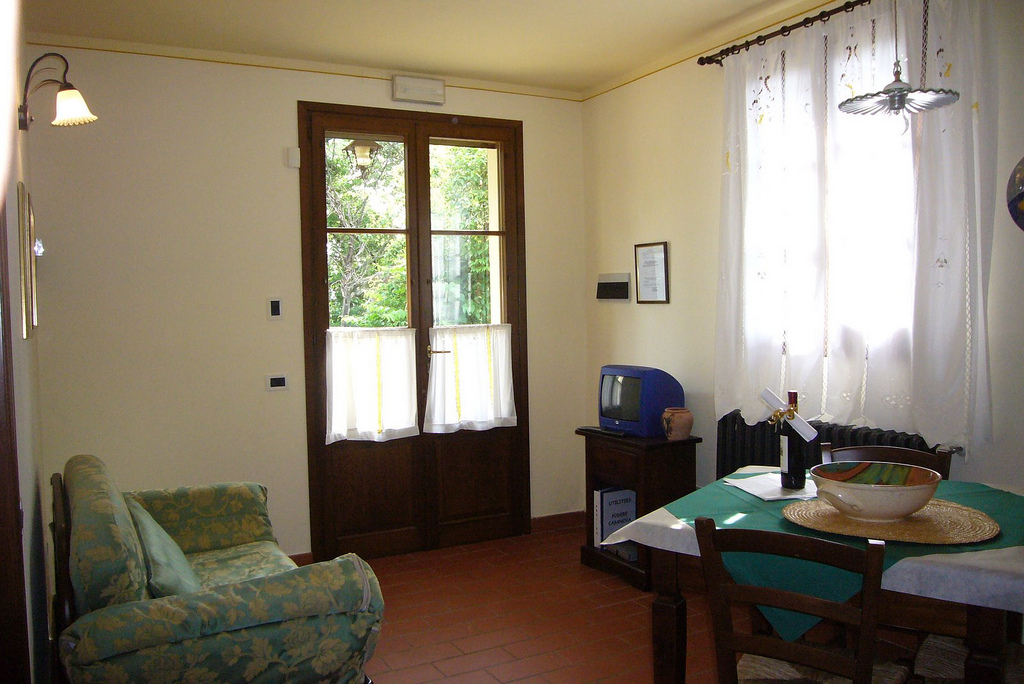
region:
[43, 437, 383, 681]
A chair against a wall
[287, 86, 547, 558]
a door with windows in it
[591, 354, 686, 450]
blue tv on a stand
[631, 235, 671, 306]
picture on a wall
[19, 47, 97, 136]
a light attached to a wall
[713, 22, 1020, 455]
curtains covering a window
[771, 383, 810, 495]
a wine bottle on a table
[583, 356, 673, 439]
blue television on stand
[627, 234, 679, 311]
frame on the wall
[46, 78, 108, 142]
light hanging on wall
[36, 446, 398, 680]
green and yellow couch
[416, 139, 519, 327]
glass window on door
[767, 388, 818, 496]
bottle on the table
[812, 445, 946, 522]
bowl on the table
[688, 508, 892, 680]
wooden chair in room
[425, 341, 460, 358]
handle on the door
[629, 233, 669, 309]
picture hanging on the wall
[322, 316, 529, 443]
curtain on the door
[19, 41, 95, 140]
a light hanging on the wall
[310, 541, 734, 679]
the floor is made of red bricks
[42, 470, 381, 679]
the couch is gold and teal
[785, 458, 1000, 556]
the bowl is on the straw mat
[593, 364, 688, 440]
the television is turned off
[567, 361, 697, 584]
the television is on a wood stand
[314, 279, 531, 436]
two white curtains on the doors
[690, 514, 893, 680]
the wooden back of a chair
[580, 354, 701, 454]
A blue TV is turned off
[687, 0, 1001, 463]
White curtains covering a window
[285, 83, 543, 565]
Two doors with glass windows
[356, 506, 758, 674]
Brown tiles on the floor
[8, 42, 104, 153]
A light fixture hanging on the wall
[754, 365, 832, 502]
A bottle of wine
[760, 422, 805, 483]
White label on the bottle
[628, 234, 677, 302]
picture hanging on the wall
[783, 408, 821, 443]
white tag on the table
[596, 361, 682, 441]
the tv is blue and turned off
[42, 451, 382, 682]
the sofa is blue with yellow flowers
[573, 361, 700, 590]
the tv on the stand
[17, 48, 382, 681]
the light above the sofa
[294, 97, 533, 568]
the curtains hanging on the doors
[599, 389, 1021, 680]
the chairs around the table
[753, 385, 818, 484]
the rolled paper on the wine bottle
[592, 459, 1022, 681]
the large bowl on the table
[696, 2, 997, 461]
the curtains hanging on the rod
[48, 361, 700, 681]
the sofa across the tv on the stand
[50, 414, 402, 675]
a floral print sofa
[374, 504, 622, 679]
a red brick floor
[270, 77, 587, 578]
a brown set of doors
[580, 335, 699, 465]
a small blue tv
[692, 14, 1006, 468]
a white sheer curtain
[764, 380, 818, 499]
bottle on the table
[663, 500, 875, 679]
a back of a dining chair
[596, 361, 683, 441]
a small blue tv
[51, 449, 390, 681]
a floral designed couch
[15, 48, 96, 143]
a light fixture on the wall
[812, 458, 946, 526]
a large glass bowl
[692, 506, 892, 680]
a wooden dining chair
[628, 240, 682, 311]
a picture frame on the wall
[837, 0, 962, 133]
a hanging light fixture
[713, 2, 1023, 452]
a white window curtain